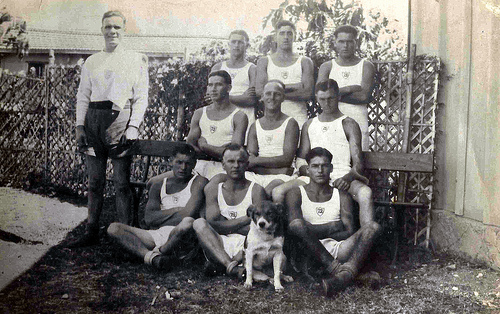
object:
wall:
[407, 2, 498, 264]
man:
[295, 78, 366, 193]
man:
[318, 25, 370, 157]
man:
[192, 142, 270, 275]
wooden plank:
[361, 149, 434, 173]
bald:
[263, 79, 284, 88]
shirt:
[72, 51, 149, 138]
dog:
[238, 204, 291, 291]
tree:
[265, 0, 393, 60]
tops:
[141, 170, 205, 220]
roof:
[15, 29, 222, 60]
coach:
[72, 9, 149, 245]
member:
[247, 81, 299, 173]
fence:
[5, 49, 434, 249]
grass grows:
[120, 279, 129, 289]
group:
[68, 8, 385, 293]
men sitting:
[97, 144, 380, 294]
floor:
[17, 204, 49, 235]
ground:
[407, 260, 466, 292]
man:
[209, 31, 253, 105]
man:
[253, 21, 317, 99]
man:
[183, 70, 247, 169]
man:
[104, 144, 208, 269]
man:
[277, 148, 381, 293]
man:
[44, 2, 159, 258]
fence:
[0, 49, 81, 193]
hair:
[103, 10, 128, 22]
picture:
[1, 2, 497, 312]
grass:
[28, 291, 48, 312]